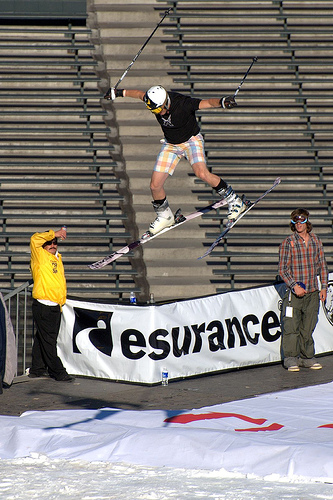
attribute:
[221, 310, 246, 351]
letter — black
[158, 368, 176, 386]
bottle — water, on ground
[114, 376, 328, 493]
tarp — white, large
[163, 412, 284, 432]
stripe — red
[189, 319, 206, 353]
letter r — black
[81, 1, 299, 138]
poles — black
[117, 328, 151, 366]
letter — black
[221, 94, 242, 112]
glove — black 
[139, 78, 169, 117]
helmet — white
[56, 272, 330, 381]
banner — black and white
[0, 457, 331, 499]
snow — fluffy, white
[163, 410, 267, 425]
stripe — red, on the bottom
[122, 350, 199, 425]
bottle — small, clear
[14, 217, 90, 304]
jacket — yellow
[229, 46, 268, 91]
ski pole — black , white 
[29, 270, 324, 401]
banner — esurance advertising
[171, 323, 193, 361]
letter — black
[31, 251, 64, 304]
jacket — yellow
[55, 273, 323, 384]
sign — white